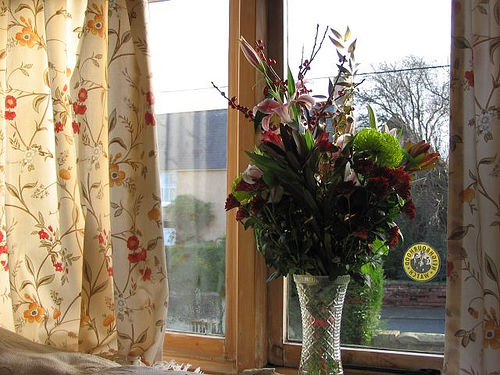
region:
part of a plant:
[273, 152, 351, 223]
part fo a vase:
[313, 302, 353, 342]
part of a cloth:
[146, 250, 172, 301]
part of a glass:
[169, 215, 178, 238]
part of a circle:
[396, 253, 408, 318]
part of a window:
[420, 288, 436, 298]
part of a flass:
[308, 290, 345, 335]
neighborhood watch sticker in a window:
[400, 238, 445, 283]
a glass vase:
[290, 272, 355, 373]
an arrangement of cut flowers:
[214, 22, 412, 279]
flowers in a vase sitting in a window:
[216, 23, 409, 370]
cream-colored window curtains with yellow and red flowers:
[1, 0, 170, 363]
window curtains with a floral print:
[2, 1, 173, 366]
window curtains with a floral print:
[446, 1, 498, 373]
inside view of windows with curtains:
[2, 2, 497, 369]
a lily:
[250, 92, 317, 137]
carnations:
[361, 163, 421, 222]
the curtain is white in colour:
[25, 18, 136, 230]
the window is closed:
[165, 3, 274, 332]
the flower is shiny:
[209, 51, 392, 277]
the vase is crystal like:
[298, 280, 346, 371]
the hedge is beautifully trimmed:
[359, 263, 374, 330]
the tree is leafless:
[378, 56, 432, 119]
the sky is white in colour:
[146, 4, 210, 88]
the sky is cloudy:
[167, 5, 214, 72]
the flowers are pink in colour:
[228, 94, 310, 196]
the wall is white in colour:
[171, 167, 213, 192]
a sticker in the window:
[399, 240, 444, 287]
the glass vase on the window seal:
[289, 272, 354, 374]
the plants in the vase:
[232, 30, 417, 271]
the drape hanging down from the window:
[2, 1, 169, 354]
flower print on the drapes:
[0, 11, 146, 341]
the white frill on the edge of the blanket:
[130, 355, 204, 374]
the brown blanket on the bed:
[0, 329, 217, 374]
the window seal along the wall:
[218, 0, 275, 370]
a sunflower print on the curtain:
[472, 316, 498, 358]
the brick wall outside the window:
[383, 280, 447, 312]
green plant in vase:
[204, 58, 348, 273]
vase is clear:
[291, 274, 345, 374]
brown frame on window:
[158, 0, 260, 364]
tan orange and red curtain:
[17, 1, 192, 338]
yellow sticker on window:
[395, 240, 442, 290]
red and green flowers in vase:
[224, 45, 421, 186]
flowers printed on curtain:
[2, 25, 140, 333]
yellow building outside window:
[155, 115, 236, 247]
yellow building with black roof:
[160, 103, 234, 188]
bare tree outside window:
[335, 68, 449, 156]